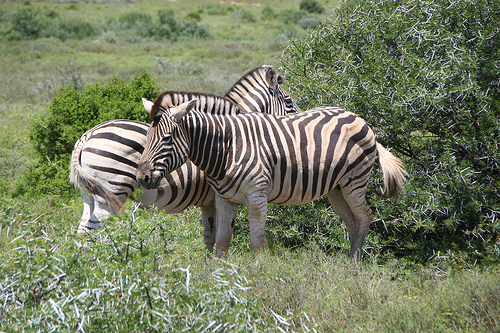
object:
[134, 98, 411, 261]
zebra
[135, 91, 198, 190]
head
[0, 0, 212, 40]
bushes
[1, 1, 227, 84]
grass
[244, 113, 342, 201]
stripes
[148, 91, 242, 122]
hair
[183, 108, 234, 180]
neck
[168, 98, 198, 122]
ear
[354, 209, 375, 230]
knee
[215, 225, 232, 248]
knee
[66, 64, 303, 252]
zebra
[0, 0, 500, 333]
field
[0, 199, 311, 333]
bush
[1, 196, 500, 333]
grass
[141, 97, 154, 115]
ears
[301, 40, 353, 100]
leaves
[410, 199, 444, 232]
leaves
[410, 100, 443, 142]
leaves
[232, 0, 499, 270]
tree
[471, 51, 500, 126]
leaves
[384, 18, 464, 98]
leaves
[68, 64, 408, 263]
each other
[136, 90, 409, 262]
left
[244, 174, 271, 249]
leg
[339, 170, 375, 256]
leg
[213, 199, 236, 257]
leg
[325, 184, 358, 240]
leg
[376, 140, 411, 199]
tail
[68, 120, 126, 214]
tail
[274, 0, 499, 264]
bush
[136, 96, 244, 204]
front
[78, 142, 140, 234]
back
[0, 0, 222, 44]
line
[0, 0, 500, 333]
plain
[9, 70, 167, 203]
bush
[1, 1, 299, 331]
ground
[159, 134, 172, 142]
eye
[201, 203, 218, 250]
legs